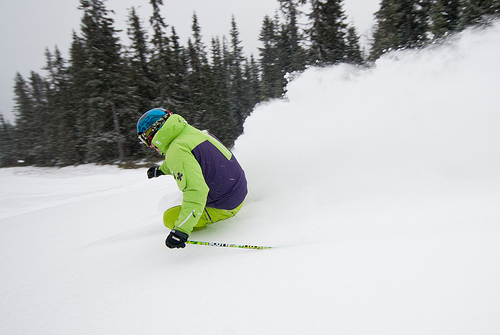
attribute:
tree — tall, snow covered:
[78, 2, 143, 166]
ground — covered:
[9, 167, 495, 334]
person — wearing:
[156, 125, 260, 245]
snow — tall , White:
[4, 17, 497, 332]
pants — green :
[166, 205, 246, 233]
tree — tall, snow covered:
[14, 67, 49, 164]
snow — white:
[293, 109, 481, 238]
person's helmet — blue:
[134, 107, 166, 137]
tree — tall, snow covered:
[342, 24, 362, 71]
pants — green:
[123, 207, 232, 229]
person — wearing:
[124, 101, 252, 253]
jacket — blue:
[150, 112, 250, 227]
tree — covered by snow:
[257, 12, 287, 99]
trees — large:
[45, 42, 156, 94]